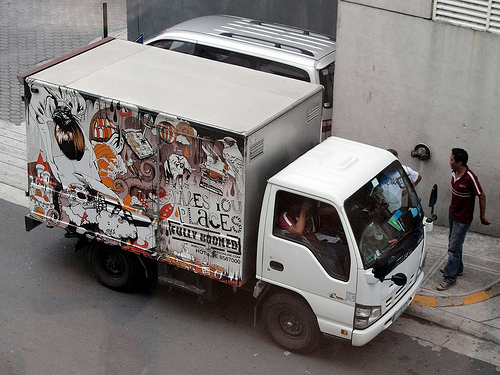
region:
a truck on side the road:
[14, 26, 442, 359]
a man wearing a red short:
[431, 140, 496, 297]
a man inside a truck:
[262, 186, 342, 273]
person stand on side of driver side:
[379, 140, 430, 219]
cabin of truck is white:
[256, 125, 438, 353]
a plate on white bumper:
[347, 275, 431, 346]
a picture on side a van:
[14, 68, 249, 285]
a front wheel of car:
[246, 280, 323, 359]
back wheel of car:
[79, 236, 153, 296]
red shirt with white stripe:
[442, 168, 484, 220]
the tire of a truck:
[264, 290, 317, 350]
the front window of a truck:
[340, 172, 422, 260]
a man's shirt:
[445, 167, 486, 218]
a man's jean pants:
[440, 218, 472, 282]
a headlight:
[356, 303, 382, 330]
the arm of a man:
[275, 200, 307, 241]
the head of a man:
[447, 145, 472, 174]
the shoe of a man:
[437, 275, 455, 293]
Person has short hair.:
[450, 145, 476, 181]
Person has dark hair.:
[446, 144, 477, 173]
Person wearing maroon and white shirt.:
[433, 170, 499, 221]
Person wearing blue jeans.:
[438, 230, 483, 283]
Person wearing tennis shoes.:
[433, 274, 459, 301]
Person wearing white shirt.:
[398, 164, 429, 186]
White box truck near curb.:
[67, 72, 412, 316]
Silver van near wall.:
[248, 30, 343, 75]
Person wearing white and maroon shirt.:
[286, 207, 321, 251]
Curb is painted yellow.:
[455, 277, 496, 307]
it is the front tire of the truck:
[263, 298, 315, 349]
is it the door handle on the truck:
[265, 260, 290, 277]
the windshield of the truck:
[348, 183, 408, 250]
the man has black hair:
[452, 145, 471, 163]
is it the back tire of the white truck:
[90, 240, 132, 288]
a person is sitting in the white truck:
[283, 200, 318, 242]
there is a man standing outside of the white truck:
[439, 148, 494, 296]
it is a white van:
[169, 10, 324, 55]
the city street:
[19, 273, 108, 371]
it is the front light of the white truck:
[348, 299, 380, 333]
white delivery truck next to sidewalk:
[16, 30, 423, 353]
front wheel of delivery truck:
[256, 289, 321, 354]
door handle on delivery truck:
[267, 261, 285, 272]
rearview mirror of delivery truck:
[427, 186, 437, 223]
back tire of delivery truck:
[87, 247, 144, 292]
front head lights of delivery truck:
[352, 301, 380, 328]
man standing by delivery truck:
[434, 147, 492, 290]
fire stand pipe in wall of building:
[410, 144, 430, 161]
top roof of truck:
[20, 37, 327, 134]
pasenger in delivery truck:
[280, 193, 347, 258]